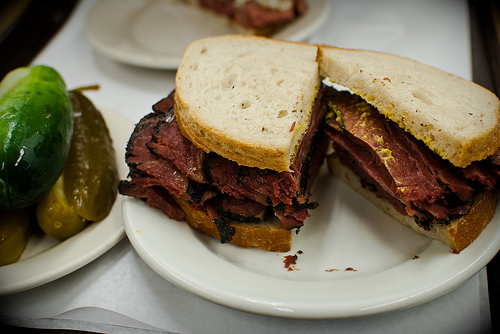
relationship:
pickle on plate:
[50, 79, 107, 230] [0, 100, 139, 283]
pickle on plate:
[21, 111, 153, 245] [1, 206, 158, 277]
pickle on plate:
[0, 63, 80, 217] [0, 103, 134, 297]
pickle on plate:
[62, 88, 118, 222] [1, 59, 131, 301]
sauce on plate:
[287, 242, 307, 274] [118, 109, 496, 319]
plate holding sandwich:
[123, 168, 497, 318] [118, 19, 493, 281]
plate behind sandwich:
[81, 2, 331, 73] [133, 25, 498, 261]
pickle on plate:
[62, 88, 118, 222] [0, 100, 139, 283]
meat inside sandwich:
[139, 143, 273, 210] [133, 25, 498, 261]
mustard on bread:
[360, 87, 428, 148] [324, 43, 499, 160]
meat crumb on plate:
[281, 252, 303, 270] [146, 40, 498, 307]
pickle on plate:
[62, 88, 118, 222] [123, 168, 497, 318]